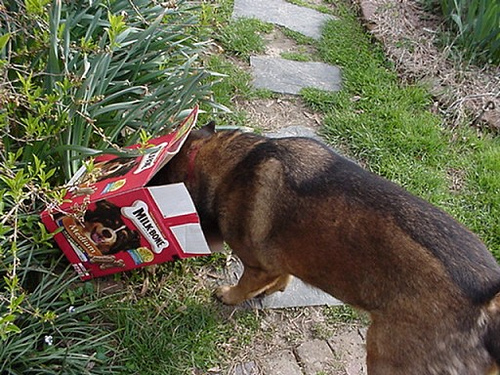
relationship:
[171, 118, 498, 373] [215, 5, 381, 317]
dog standing on path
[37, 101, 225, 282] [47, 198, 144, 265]
red box with dog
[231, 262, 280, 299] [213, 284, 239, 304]
leg has paws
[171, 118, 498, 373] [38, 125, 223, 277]
dog in a box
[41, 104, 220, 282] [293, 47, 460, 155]
red box on ground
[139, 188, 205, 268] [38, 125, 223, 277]
flap on box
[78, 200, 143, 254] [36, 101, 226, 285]
dog on box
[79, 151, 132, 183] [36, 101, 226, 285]
dog on box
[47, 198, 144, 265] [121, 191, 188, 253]
dog of bone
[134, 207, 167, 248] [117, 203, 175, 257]
lettering on bone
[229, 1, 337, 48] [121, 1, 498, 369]
tile on ground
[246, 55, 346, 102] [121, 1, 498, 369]
tile on ground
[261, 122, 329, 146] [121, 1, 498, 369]
tile on ground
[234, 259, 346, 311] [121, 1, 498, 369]
tile on ground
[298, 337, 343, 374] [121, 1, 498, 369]
tile on ground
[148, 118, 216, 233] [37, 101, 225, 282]
dog's head in red box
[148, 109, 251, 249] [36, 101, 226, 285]
dog's head in box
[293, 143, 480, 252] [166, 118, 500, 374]
back of dog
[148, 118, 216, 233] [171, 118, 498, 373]
dog's head of dog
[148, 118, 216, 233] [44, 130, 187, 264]
dog's head in box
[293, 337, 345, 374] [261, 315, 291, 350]
tile lying on mud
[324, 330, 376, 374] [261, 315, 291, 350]
brick lying on mud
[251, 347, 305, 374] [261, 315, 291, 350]
stones lying on mud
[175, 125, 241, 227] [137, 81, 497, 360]
collar of dog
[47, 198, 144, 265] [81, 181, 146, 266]
dog of head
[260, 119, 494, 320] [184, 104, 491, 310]
streak on back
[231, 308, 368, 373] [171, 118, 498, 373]
stones under dog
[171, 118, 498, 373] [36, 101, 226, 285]
dog in box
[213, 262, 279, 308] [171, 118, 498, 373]
leg of dog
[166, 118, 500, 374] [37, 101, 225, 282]
dog in red box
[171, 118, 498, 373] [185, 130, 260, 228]
dog with neck